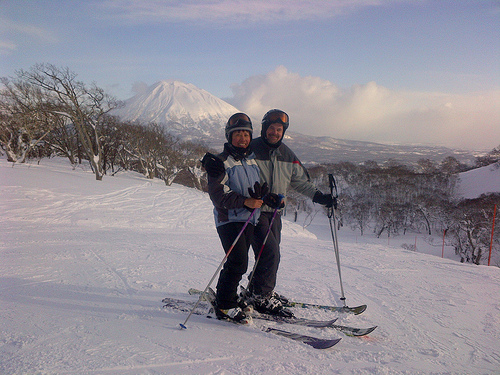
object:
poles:
[177, 205, 258, 332]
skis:
[161, 300, 342, 350]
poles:
[322, 201, 352, 312]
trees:
[5, 59, 116, 181]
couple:
[202, 104, 297, 324]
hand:
[245, 199, 263, 208]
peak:
[144, 78, 193, 92]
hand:
[312, 190, 338, 208]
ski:
[187, 287, 367, 314]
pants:
[212, 222, 250, 309]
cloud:
[299, 61, 446, 143]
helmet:
[226, 113, 254, 134]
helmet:
[261, 108, 290, 128]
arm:
[201, 151, 220, 172]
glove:
[247, 180, 270, 200]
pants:
[247, 208, 282, 297]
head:
[229, 124, 252, 149]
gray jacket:
[250, 141, 320, 214]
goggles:
[263, 111, 290, 124]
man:
[250, 108, 337, 318]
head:
[264, 116, 284, 143]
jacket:
[208, 148, 264, 227]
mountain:
[118, 71, 241, 142]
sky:
[5, 0, 495, 145]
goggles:
[227, 113, 252, 126]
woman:
[209, 110, 283, 328]